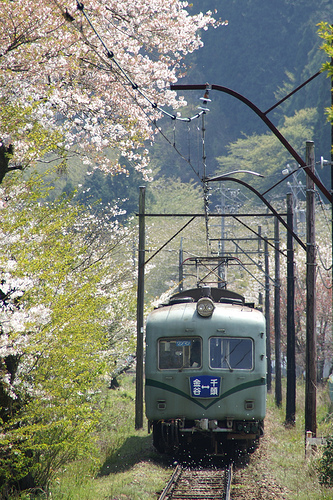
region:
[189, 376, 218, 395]
blue and white sticker on front of train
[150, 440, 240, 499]
tracks train is traveling down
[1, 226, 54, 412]
tree with white flowers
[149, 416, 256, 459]
wheels on the train car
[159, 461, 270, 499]
gravel around the train tracks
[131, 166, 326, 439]
utility poles on both sides of the track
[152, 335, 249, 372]
front windows on the train car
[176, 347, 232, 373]
windshield wipers on train car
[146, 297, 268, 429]
light green train car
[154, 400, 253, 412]
lights on front of train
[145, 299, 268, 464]
Green train on the train tracks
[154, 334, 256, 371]
Window of the green train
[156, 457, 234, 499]
Train tracks near the train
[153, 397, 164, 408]
right head light of the train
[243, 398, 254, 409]
left head light of the train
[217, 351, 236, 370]
left wiper of the window of the train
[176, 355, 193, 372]
right wiper of the window of the train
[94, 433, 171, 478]
Shadow of the green train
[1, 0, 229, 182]
Light pink flowers on the branch of the tree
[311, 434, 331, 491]
Small green shrub near the train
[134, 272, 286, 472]
train on the tracks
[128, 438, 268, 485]
petals falling to the ground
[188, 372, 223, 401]
blue and white sign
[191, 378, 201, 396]
Chinese characters on the sign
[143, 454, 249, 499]
train tracks on the ground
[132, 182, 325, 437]
poles along the train tracks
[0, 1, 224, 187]
cherry blossoms on the tree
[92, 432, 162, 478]
shadow from the train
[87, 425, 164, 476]
shadow on the ground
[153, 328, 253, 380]
windows on the train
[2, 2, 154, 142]
Pink cherry blossoms in the trees.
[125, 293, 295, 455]
A green train on the tracks.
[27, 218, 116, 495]
Green bushes in the field.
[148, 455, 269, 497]
The train tracks run through the medow.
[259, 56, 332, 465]
Telephone poles run along the train tracks.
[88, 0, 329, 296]
It looks like a sunny spring day.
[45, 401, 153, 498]
The grass is starting to grow.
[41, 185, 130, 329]
The trees are starting to bloom.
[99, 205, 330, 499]
The train is coming.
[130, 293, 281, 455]
The train is green with an asian symbol on the front.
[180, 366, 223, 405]
blue sign on the train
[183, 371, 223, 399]
white foreign letters on train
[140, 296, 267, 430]
the train is green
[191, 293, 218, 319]
light on top of train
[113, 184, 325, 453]
wooden poles on sides of train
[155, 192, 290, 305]
metal structures above the train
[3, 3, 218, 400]
flowers on the trees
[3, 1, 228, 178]
the flowers are pink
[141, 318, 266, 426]
front of train is dirty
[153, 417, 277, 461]
base of train is brown